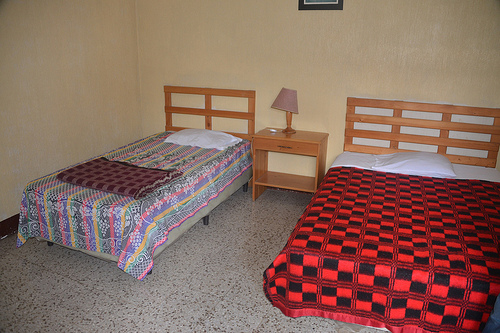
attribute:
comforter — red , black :
[257, 154, 499, 331]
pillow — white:
[162, 123, 242, 153]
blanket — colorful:
[16, 131, 253, 278]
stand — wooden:
[248, 126, 328, 203]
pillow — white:
[365, 143, 463, 185]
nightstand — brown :
[245, 121, 329, 202]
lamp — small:
[270, 88, 297, 134]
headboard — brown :
[162, 82, 256, 143]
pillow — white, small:
[378, 144, 458, 181]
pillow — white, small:
[168, 121, 245, 149]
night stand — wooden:
[248, 127, 326, 199]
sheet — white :
[8, 122, 258, 275]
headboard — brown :
[160, 84, 257, 135]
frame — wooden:
[342, 97, 498, 166]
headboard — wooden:
[339, 89, 499, 173]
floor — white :
[2, 185, 385, 329]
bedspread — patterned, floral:
[16, 131, 252, 281]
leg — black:
[202, 212, 210, 225]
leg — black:
[241, 181, 250, 193]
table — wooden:
[267, 124, 314, 173]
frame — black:
[281, 1, 356, 21]